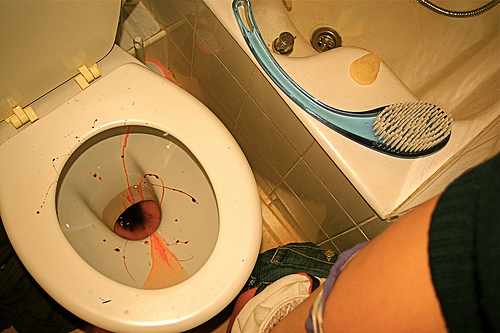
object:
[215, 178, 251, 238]
toilet seat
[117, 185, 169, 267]
blood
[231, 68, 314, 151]
tiles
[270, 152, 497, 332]
person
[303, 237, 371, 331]
underwear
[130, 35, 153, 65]
handle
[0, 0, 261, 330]
toilet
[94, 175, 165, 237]
blood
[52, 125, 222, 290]
toilet bowl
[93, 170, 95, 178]
blood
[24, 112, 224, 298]
toilet bowl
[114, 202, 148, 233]
blood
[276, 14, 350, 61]
faucet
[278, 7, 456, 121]
tub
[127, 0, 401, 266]
tiles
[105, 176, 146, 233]
blood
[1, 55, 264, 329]
toilet bowl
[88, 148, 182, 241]
red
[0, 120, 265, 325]
toilet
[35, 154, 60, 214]
blood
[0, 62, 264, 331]
toilet seat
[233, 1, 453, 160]
scrub brush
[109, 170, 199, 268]
blood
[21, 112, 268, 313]
toilet bowl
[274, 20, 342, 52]
drain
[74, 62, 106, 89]
white hinge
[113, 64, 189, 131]
toilet seat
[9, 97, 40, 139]
hinge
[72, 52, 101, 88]
hinge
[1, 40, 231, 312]
toilet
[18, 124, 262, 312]
toilet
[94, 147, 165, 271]
blood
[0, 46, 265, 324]
bowl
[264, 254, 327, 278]
jeans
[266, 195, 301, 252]
floor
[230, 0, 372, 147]
handle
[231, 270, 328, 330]
tennis shoe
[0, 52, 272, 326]
toilet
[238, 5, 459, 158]
brush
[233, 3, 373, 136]
handle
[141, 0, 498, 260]
bathtub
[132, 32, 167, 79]
toilet brush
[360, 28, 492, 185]
showers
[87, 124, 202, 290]
orange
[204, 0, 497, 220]
shelf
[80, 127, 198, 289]
blood